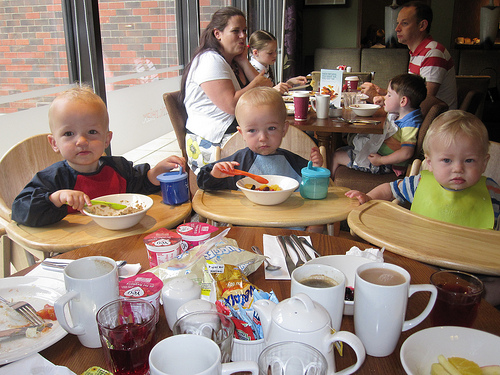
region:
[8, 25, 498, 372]
three little toddlers together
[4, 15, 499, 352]
toddlers are sitting in high chairs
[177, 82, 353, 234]
toddler holding a spoon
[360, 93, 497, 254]
baby wearing a bib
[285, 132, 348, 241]
a light blue sippee cup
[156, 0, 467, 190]
a family sitting in background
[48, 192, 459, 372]
multiple cups on the table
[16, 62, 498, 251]
Three baby boys in high chairs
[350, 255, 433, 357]
A tall cup of coffee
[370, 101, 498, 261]
A little boy sitting in a high chair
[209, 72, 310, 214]
A little boy holding an orange spoon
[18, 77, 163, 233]
A little boy wearing a blue and red top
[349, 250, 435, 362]
Hot chocolate in a white cup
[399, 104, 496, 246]
A little boy wearing a yellow bib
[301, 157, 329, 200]
a blue sippy cup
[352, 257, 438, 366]
a tall white coffee mug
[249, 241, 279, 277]
a silver spoon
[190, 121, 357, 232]
part of a wooden highchair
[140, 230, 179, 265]
a yogurt cup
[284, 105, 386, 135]
part of a brown wooden table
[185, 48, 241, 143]
part of a woman's white sweater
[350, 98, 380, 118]
a white bowl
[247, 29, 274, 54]
a girl's hair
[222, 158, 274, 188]
orange spoon in baby's hand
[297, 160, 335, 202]
small blue cup with lid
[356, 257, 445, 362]
large cup of white coffee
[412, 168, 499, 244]
green bib around baby's neck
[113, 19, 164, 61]
red and black bricks on the wall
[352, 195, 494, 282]
brown wooden baby's table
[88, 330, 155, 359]
red liquid in clear glass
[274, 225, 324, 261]
set of silverware on napkin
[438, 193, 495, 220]
GREEN BIB ON THE BABY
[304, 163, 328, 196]
BLUE CUP ON THE TRAY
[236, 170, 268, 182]
BABY HOLDING A ORANGE SPOON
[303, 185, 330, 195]
MILK IN THE CUP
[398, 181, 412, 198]
STRIPE ON THE SHIRT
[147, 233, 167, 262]
CEREAL IN THE CUP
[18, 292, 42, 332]
FORK LAYING ON THE PLATE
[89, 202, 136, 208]
BABY HOLDING A GREEN SPOON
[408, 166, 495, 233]
baby wearing green bib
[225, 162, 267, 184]
boy has an orange spoon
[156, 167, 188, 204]
the sippy cup is blue